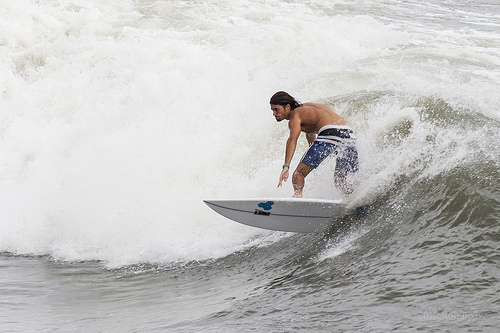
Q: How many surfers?
A: One.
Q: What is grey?
A: Water.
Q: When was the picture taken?
A: Daytime.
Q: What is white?
A: Surfboard.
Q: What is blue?
A: Shorts.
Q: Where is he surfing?
A: Ocean.